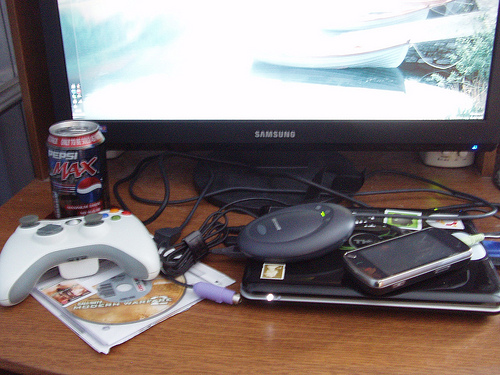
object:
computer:
[27, 0, 500, 157]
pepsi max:
[43, 117, 110, 224]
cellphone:
[338, 224, 475, 297]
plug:
[450, 225, 489, 249]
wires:
[356, 178, 464, 200]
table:
[2, 136, 499, 374]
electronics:
[0, 206, 165, 311]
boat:
[227, 13, 417, 84]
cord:
[123, 152, 192, 221]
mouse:
[230, 198, 357, 265]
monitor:
[33, 0, 500, 151]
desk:
[0, 139, 498, 374]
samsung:
[253, 127, 301, 141]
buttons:
[17, 210, 42, 231]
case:
[28, 233, 241, 360]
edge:
[238, 291, 500, 313]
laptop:
[238, 199, 500, 319]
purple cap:
[188, 280, 244, 307]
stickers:
[381, 208, 424, 232]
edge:
[339, 250, 382, 293]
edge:
[70, 127, 497, 151]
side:
[95, 131, 112, 213]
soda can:
[41, 117, 112, 218]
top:
[45, 117, 100, 138]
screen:
[53, 0, 499, 121]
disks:
[35, 235, 236, 356]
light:
[468, 143, 481, 152]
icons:
[68, 81, 87, 119]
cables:
[206, 186, 231, 199]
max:
[47, 155, 101, 183]